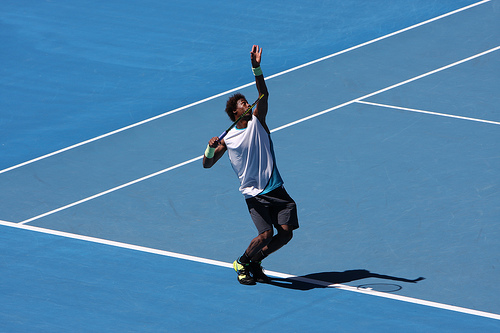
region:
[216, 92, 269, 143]
Small black plastic tennis racket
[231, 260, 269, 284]
Black and yellow athletic shoes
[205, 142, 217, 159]
Small wide white wrist band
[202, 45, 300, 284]
Black man with a tennis racket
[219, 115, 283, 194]
White cut off sleeve shirt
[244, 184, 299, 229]
Small knee length black shorts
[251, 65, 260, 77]
Small rectangular cloth wrist band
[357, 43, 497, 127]
white and blue square section of tennis court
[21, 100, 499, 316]
Large blue section of tennis court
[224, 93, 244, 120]
Black puffy curly hair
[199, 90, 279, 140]
this is a racket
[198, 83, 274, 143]
the racket is big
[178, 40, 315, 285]
this is a man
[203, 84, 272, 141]
the man is holding a racket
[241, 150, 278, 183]
this is a vest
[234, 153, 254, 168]
the vest is white in color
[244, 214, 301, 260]
the knees are bent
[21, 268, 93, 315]
this is the ground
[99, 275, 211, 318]
the ground is blue in color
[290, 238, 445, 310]
this is a shadow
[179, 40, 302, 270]
this is a man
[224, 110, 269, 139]
this is a racket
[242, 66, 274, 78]
this is a wrist band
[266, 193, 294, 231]
this is a short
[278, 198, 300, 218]
the short is black in color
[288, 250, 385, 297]
this is the shadow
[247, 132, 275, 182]
this is a vest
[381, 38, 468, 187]
this is the playing ground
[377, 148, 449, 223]
the ground is blue in color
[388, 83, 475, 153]
this is a white strip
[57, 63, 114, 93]
this is the floor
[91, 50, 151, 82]
the floor is blue in color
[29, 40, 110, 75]
the floor is clean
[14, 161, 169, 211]
this is a tennis pitch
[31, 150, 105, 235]
the pitch has markings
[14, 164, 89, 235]
the markings are white in color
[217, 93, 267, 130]
this is a racket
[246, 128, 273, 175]
the vest is white in color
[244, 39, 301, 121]
the hand is raised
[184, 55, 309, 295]
this is a tennis player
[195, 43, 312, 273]
he is swinging the racket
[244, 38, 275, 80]
the hand is in above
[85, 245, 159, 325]
this is the pitch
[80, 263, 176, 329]
the pitch is blue in color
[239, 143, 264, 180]
this is the jersey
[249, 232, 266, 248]
the player is dark skinned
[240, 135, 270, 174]
the jersey is white in color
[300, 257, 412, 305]
this is the shadow